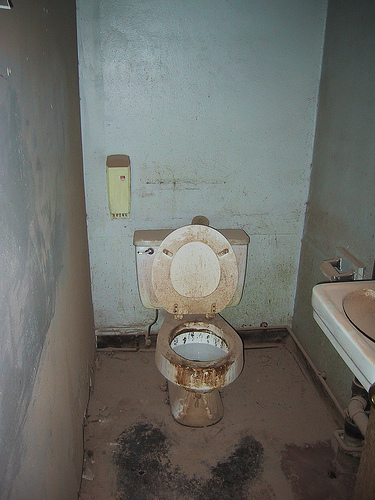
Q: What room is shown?
A: It is a bathroom.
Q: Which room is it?
A: It is a bathroom.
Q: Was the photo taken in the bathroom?
A: Yes, it was taken in the bathroom.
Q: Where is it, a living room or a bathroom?
A: It is a bathroom.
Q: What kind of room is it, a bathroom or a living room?
A: It is a bathroom.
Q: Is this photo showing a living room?
A: No, the picture is showing a bathroom.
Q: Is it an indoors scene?
A: Yes, it is indoors.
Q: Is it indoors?
A: Yes, it is indoors.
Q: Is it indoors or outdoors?
A: It is indoors.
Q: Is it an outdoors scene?
A: No, it is indoors.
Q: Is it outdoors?
A: No, it is indoors.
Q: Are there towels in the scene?
A: No, there are no towels.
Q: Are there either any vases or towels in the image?
A: No, there are no towels or vases.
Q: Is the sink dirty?
A: Yes, the sink is dirty.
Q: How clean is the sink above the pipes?
A: The sink is dirty.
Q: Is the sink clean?
A: No, the sink is dirty.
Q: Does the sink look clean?
A: No, the sink is dirty.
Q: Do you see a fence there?
A: No, there are no fences.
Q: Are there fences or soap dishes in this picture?
A: No, there are no fences or soap dishes.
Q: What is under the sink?
A: The pipes are under the sink.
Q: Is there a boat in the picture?
A: No, there are no boats.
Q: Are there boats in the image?
A: No, there are no boats.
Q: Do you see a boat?
A: No, there are no boats.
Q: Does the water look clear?
A: Yes, the water is clear.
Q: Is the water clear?
A: Yes, the water is clear.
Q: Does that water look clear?
A: Yes, the water is clear.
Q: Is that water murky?
A: No, the water is clear.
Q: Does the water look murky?
A: No, the water is clear.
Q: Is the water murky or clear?
A: The water is clear.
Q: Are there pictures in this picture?
A: No, there are no pictures.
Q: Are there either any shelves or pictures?
A: No, there are no pictures or shelves.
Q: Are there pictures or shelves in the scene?
A: No, there are no pictures or shelves.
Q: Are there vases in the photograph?
A: No, there are no vases.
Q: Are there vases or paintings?
A: No, there are no vases or paintings.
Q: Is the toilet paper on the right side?
A: Yes, the toilet paper is on the right of the image.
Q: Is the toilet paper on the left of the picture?
A: No, the toilet paper is on the right of the image.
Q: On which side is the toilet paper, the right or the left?
A: The toilet paper is on the right of the image.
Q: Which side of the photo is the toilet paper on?
A: The toilet paper is on the right of the image.